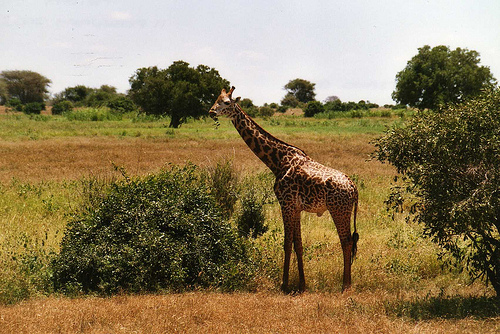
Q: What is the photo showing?
A: It is showing a field.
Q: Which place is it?
A: It is a field.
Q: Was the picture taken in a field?
A: Yes, it was taken in a field.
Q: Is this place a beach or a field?
A: It is a field.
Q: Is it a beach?
A: No, it is a field.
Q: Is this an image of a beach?
A: No, the picture is showing a field.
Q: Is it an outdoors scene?
A: Yes, it is outdoors.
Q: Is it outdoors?
A: Yes, it is outdoors.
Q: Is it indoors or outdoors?
A: It is outdoors.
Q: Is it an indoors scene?
A: No, it is outdoors.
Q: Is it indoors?
A: No, it is outdoors.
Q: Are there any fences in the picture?
A: No, there are no fences.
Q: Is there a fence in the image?
A: No, there are no fences.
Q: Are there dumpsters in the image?
A: No, there are no dumpsters.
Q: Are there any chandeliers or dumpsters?
A: No, there are no dumpsters or chandeliers.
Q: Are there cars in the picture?
A: No, there are no cars.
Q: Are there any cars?
A: No, there are no cars.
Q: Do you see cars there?
A: No, there are no cars.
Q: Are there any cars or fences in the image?
A: No, there are no cars or fences.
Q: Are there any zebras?
A: No, there are no zebras.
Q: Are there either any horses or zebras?
A: No, there are no zebras or horses.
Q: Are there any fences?
A: No, there are no fences.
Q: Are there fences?
A: No, there are no fences.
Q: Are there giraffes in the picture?
A: Yes, there is a giraffe.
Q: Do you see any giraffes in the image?
A: Yes, there is a giraffe.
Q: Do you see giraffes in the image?
A: Yes, there is a giraffe.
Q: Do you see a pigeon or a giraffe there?
A: Yes, there is a giraffe.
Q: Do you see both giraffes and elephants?
A: No, there is a giraffe but no elephants.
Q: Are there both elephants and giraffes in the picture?
A: No, there is a giraffe but no elephants.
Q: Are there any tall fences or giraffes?
A: Yes, there is a tall giraffe.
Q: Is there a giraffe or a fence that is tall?
A: Yes, the giraffe is tall.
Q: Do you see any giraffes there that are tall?
A: Yes, there is a tall giraffe.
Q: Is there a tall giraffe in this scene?
A: Yes, there is a tall giraffe.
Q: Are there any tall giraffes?
A: Yes, there is a tall giraffe.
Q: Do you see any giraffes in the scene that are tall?
A: Yes, there is a giraffe that is tall.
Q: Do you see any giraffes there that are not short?
A: Yes, there is a tall giraffe.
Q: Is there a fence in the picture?
A: No, there are no fences.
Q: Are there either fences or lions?
A: No, there are no fences or lions.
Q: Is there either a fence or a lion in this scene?
A: No, there are no fences or lions.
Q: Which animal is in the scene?
A: The animal is a giraffe.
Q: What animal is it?
A: The animal is a giraffe.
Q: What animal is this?
A: That is a giraffe.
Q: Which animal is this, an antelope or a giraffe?
A: That is a giraffe.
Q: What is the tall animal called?
A: The animal is a giraffe.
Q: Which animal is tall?
A: The animal is a giraffe.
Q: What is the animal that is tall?
A: The animal is a giraffe.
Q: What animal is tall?
A: The animal is a giraffe.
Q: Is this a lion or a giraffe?
A: This is a giraffe.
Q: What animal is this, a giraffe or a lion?
A: This is a giraffe.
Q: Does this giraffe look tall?
A: Yes, the giraffe is tall.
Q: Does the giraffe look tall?
A: Yes, the giraffe is tall.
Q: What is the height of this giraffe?
A: The giraffe is tall.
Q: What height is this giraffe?
A: The giraffe is tall.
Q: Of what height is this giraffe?
A: The giraffe is tall.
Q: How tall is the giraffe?
A: The giraffe is tall.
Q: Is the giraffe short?
A: No, the giraffe is tall.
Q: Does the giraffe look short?
A: No, the giraffe is tall.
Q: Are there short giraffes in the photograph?
A: No, there is a giraffe but it is tall.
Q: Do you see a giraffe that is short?
A: No, there is a giraffe but it is tall.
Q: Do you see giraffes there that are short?
A: No, there is a giraffe but it is tall.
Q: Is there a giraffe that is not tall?
A: No, there is a giraffe but it is tall.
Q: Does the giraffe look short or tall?
A: The giraffe is tall.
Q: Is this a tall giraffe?
A: Yes, this is a tall giraffe.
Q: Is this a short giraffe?
A: No, this is a tall giraffe.